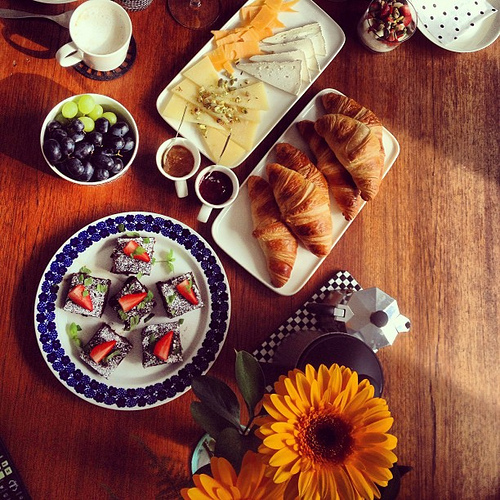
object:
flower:
[250, 359, 401, 499]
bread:
[244, 173, 299, 288]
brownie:
[110, 233, 158, 281]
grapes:
[62, 155, 87, 177]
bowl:
[38, 91, 142, 187]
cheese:
[160, 55, 270, 167]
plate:
[154, 0, 347, 168]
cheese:
[234, 18, 329, 97]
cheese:
[205, 0, 299, 79]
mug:
[55, 0, 134, 72]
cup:
[193, 162, 241, 225]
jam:
[198, 169, 235, 204]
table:
[0, 0, 500, 499]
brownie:
[141, 318, 186, 370]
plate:
[32, 209, 234, 411]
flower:
[177, 448, 288, 500]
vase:
[189, 423, 256, 474]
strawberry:
[70, 282, 95, 314]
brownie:
[60, 270, 113, 320]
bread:
[266, 160, 335, 260]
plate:
[209, 86, 403, 297]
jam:
[160, 144, 195, 179]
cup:
[154, 135, 202, 200]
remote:
[1, 440, 34, 498]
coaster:
[70, 32, 140, 82]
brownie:
[75, 320, 137, 379]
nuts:
[203, 92, 221, 111]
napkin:
[251, 268, 363, 365]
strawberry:
[176, 281, 199, 306]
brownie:
[156, 269, 208, 319]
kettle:
[270, 328, 388, 405]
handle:
[306, 303, 345, 322]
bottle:
[303, 285, 413, 350]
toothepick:
[161, 102, 188, 168]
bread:
[294, 116, 364, 224]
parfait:
[359, 0, 417, 53]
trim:
[37, 272, 59, 345]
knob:
[369, 308, 387, 326]